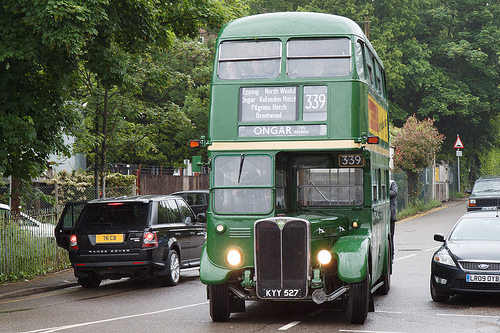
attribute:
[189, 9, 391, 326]
double decker bus — double decker, green, large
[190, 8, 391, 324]
green bus — double decker, old fashioned, city bus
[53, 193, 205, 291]
range rover — black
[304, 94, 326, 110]
numbers 339 — black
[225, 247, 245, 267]
headlight — on, bright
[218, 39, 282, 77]
bus's window — second level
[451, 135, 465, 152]
street sign — red, white, triangle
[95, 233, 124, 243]
registration plate — yellow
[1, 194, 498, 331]
pavement — wet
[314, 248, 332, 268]
headlight — on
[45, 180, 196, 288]
suv — parked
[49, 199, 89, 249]
door — open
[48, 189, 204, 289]
suv — black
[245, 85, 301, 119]
letters — white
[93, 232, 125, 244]
plate — licence